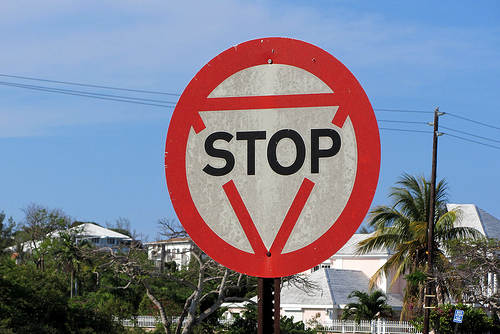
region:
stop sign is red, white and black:
[186, 48, 368, 276]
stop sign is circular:
[159, 39, 382, 276]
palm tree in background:
[385, 177, 467, 297]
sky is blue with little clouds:
[27, 27, 154, 62]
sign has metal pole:
[253, 280, 285, 327]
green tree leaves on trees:
[8, 265, 113, 320]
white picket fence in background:
[325, 320, 415, 332]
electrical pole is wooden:
[420, 104, 449, 263]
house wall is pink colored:
[347, 258, 381, 270]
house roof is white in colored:
[76, 222, 126, 240]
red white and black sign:
[185, 37, 362, 288]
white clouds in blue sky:
[9, 14, 71, 55]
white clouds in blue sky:
[5, 64, 79, 132]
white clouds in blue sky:
[11, 114, 59, 161]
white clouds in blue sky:
[68, 168, 140, 210]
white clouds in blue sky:
[63, 94, 135, 148]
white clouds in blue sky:
[78, 27, 172, 94]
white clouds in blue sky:
[325, 4, 390, 44]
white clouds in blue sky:
[405, 11, 476, 62]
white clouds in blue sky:
[373, 46, 411, 108]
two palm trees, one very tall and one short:
[340, 166, 472, 328]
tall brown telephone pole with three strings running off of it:
[399, 106, 464, 327]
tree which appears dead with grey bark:
[142, 256, 227, 332]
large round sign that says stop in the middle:
[165, 29, 385, 282]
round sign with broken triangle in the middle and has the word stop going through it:
[155, 34, 381, 284]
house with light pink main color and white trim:
[221, 266, 380, 331]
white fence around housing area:
[300, 316, 440, 326]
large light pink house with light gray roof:
[332, 200, 497, 321]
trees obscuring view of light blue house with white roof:
[5, 202, 145, 328]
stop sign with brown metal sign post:
[157, 36, 384, 332]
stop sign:
[203, 50, 380, 263]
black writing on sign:
[204, 128, 387, 176]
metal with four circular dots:
[254, 273, 289, 332]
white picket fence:
[314, 315, 421, 331]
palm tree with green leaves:
[342, 286, 401, 325]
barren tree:
[92, 230, 239, 329]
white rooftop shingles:
[292, 269, 389, 317]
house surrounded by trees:
[38, 214, 160, 287]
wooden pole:
[424, 110, 449, 332]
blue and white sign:
[440, 307, 470, 331]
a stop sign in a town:
[161, 34, 382, 276]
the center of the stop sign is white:
[184, 58, 361, 257]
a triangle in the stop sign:
[188, 87, 349, 259]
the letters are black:
[197, 125, 345, 179]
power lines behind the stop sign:
[6, 72, 496, 151]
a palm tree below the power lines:
[359, 159, 480, 329]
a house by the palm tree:
[274, 228, 441, 330]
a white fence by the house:
[287, 316, 422, 331]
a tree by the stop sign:
[79, 237, 233, 332]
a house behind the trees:
[6, 217, 136, 262]